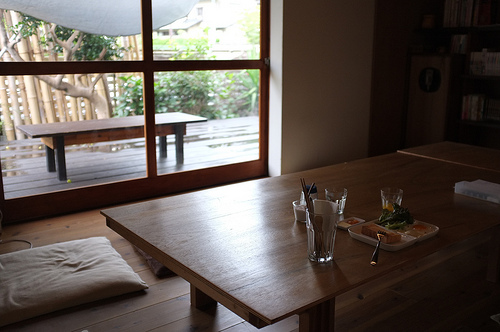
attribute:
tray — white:
[351, 206, 420, 256]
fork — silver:
[365, 233, 390, 266]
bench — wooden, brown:
[32, 107, 194, 176]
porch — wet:
[12, 110, 256, 193]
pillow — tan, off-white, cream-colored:
[1, 223, 112, 311]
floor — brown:
[5, 228, 289, 331]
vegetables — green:
[383, 204, 416, 231]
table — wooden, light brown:
[89, 135, 495, 330]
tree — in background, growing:
[21, 32, 247, 114]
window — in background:
[8, 2, 272, 211]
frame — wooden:
[2, 1, 273, 161]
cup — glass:
[307, 207, 337, 266]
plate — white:
[356, 214, 426, 253]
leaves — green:
[135, 74, 231, 119]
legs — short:
[178, 275, 221, 316]